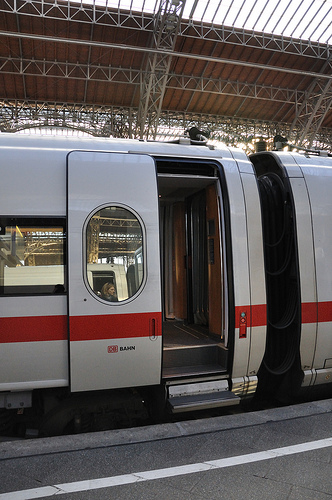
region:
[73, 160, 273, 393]
The train door is open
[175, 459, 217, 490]
White paint on the sidewalk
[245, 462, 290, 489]
Cracks in the pavement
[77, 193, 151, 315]
Window on the door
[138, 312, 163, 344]
Handle on the train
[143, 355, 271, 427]
Stairs on the train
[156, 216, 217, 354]
Doorway in the train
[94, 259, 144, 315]
Woman waiting for the train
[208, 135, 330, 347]
The two train cars are connected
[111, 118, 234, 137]
Metal rafters above the train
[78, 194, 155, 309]
window on train car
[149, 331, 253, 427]
steps on to a train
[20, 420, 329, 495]
white line painted on a sidewalk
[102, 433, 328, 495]
cement tile sidewalk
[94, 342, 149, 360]
company logo on side on train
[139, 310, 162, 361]
door handle on side door of train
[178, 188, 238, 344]
hallway in middle on train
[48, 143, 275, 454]
open door on train car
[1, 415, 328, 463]
curb to side walk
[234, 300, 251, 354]
control buttons on side on train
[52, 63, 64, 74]
truss of suspension bridge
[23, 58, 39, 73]
truss of suspension bridge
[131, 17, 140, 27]
truss of suspension bridge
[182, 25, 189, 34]
truss of suspension bridge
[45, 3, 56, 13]
truss of suspension bridge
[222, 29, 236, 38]
truss of suspension bridge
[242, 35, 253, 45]
truss of suspension bridge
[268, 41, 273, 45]
truss of suspension bridge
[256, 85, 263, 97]
truss of suspension bridge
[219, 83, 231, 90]
truss of suspension bridge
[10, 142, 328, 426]
a subway train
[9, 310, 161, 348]
red strip on a door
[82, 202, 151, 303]
a glass in the door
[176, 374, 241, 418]
a silver step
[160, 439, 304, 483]
a white line on concrete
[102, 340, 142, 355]
writing on a door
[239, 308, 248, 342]
buttons on a door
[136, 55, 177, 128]
a metal beam in the ceiling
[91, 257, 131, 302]
a reflection in the glass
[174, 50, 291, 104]
a rusty metal roof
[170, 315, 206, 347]
marks on the floor of the train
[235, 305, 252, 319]
small green light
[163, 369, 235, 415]
silver steps on the train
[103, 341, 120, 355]
small red symbol on train's door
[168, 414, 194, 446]
small marks at edge of platform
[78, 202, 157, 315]
window in door of train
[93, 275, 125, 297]
passenger sitting in train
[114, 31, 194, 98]
silver cables in ceiling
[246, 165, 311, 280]
black hose in middle of train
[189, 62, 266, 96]
red color in the ceiling